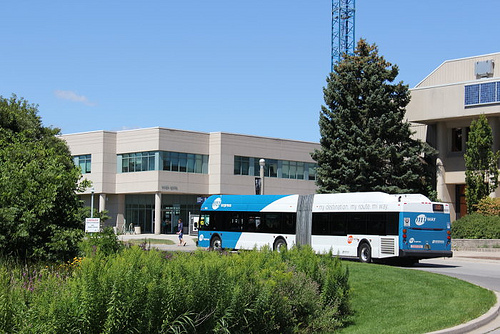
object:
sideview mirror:
[194, 221, 199, 228]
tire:
[356, 237, 371, 262]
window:
[235, 152, 243, 177]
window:
[184, 153, 195, 170]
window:
[146, 152, 154, 169]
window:
[123, 151, 130, 171]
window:
[290, 158, 305, 178]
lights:
[400, 230, 414, 240]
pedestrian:
[174, 215, 188, 250]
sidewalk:
[112, 225, 202, 251]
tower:
[329, 2, 359, 96]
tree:
[307, 37, 438, 200]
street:
[111, 232, 498, 331]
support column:
[153, 190, 160, 231]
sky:
[33, 11, 313, 113]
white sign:
[84, 214, 101, 234]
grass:
[124, 244, 485, 332]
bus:
[185, 176, 453, 278]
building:
[30, 124, 352, 254]